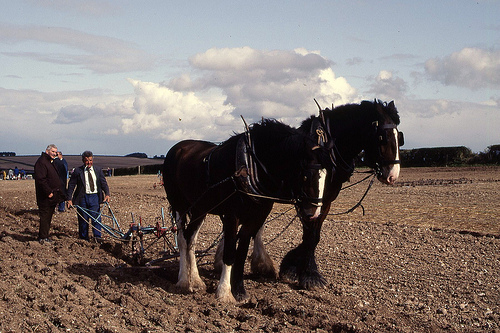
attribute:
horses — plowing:
[161, 103, 405, 301]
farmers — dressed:
[34, 143, 114, 239]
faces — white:
[312, 110, 410, 226]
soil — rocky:
[34, 222, 286, 305]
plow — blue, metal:
[74, 198, 180, 269]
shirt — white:
[84, 166, 96, 194]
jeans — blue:
[78, 194, 101, 242]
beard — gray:
[50, 154, 60, 161]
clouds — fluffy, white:
[141, 50, 328, 134]